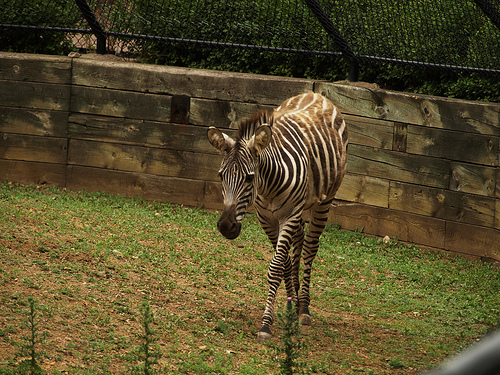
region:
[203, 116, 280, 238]
head of a zebra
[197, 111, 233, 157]
ear of a zebra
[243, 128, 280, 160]
ear of a zebra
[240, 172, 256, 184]
eye of a zebra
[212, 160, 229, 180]
eye of a zebra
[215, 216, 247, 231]
nose of a zebra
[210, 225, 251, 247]
mouth of a zebra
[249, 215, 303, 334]
leg of a zebra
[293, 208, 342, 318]
leg of a zebra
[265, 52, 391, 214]
body of a zebra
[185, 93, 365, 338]
Zebra is walking in ground.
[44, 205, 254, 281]
Grass is green color.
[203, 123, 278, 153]
Zebra has two pointed ears.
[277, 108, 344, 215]
Stripe design in zebra.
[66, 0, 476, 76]
Chain fence is black color.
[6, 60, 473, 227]
Fence is brown color.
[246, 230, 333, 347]
Zebra has four legs.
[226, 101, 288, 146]
Short hairs on zebra back.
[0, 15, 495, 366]
zebra inside of enclosure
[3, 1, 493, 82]
chainlink fence covering animal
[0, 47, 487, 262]
wooden blcok fence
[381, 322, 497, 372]
part of the metal fence railing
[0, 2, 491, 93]
trees and bushes on other side of fence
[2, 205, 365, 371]
dry patches of dirt in the field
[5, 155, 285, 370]
the bottom of a small hill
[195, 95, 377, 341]
zebra walking up small hill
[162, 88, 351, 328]
zebra bending down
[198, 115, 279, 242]
head of a zebra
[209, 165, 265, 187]
eyes of a zebra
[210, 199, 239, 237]
nose of a zebra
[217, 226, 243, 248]
mouth of a zebra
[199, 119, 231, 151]
ear of a zebra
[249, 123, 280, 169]
ear of a zebra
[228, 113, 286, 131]
hair of a zebra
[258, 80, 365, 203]
body of a zebra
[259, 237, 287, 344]
leg of a zebra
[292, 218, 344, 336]
leg of a zebra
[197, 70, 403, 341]
this is a zebra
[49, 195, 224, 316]
this is a grass area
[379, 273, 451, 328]
the grass is green in color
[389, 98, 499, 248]
this is a wall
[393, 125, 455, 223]
the wall is wooden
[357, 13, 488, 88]
this is a fence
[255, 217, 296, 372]
this is the leg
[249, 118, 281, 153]
this is the ear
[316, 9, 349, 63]
this is a pole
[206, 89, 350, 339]
striped zebra standing in grass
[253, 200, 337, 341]
zebra has four legs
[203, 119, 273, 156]
zebra has two ears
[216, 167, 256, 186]
zebra has two eyes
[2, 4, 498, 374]
zebra is standing in an enclosure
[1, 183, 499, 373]
the grass is sparse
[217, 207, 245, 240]
zebra has a brown snout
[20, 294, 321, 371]
three, small trees in front of zebra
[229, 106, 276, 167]
zebra has a fur mane